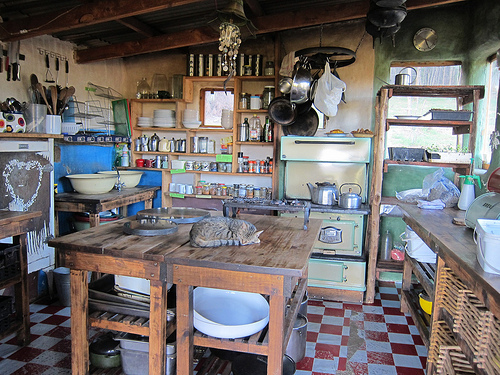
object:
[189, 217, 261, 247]
cat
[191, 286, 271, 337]
bowl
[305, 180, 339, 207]
kettle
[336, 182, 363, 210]
kettle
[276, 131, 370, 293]
stove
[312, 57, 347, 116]
bag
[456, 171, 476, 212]
bottle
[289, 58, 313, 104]
pot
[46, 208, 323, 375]
table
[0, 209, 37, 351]
table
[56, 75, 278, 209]
shelves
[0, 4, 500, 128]
wall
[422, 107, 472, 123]
pan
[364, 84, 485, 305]
shelf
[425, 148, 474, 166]
container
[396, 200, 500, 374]
counter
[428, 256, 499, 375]
baskets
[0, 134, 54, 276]
cabinet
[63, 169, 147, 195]
bowls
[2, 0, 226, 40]
beam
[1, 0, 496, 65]
ceiling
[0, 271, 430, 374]
floor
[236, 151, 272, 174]
spices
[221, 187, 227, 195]
jar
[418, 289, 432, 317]
bowl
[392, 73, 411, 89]
kettle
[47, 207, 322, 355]
shelf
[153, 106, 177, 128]
plates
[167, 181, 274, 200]
jars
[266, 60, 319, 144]
pans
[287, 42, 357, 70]
rack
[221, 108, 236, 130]
bowls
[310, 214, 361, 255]
door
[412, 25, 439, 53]
clock